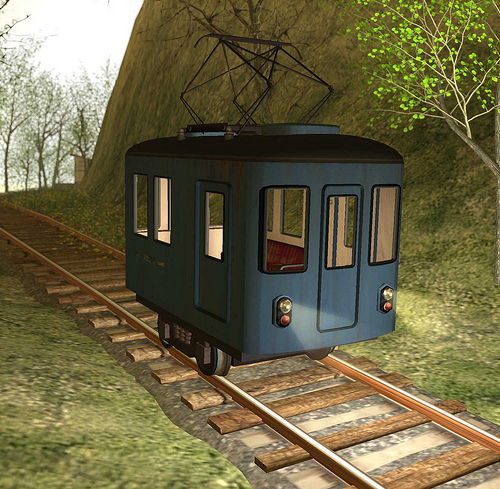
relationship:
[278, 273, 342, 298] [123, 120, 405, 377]
light on car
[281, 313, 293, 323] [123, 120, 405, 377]
light on car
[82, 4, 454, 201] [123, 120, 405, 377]
wall behind car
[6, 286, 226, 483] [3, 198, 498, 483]
grass next to track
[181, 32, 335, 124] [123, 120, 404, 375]
structure on top of car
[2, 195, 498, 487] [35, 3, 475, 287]
tracks next to hill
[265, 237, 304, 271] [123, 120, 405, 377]
seat on car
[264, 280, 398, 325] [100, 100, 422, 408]
headlights on car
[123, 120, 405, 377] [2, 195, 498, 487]
car on tracks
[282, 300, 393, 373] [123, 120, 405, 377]
light on car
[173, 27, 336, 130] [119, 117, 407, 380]
structure above cart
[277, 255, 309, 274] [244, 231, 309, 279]
railing next to seat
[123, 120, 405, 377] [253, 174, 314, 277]
car has window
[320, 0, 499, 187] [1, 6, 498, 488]
tree in photo